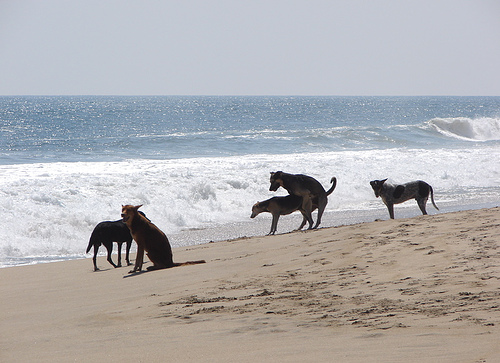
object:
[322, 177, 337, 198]
tail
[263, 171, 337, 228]
dog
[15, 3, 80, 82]
sky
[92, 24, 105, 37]
skies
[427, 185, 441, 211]
tail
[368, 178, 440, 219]
dog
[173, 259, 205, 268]
tail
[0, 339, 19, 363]
ground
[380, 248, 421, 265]
ground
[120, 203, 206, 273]
brown dogs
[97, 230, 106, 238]
black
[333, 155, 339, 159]
white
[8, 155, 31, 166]
water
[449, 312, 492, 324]
footprints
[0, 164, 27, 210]
wave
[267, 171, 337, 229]
dog humped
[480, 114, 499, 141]
wave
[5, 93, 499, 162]
ocean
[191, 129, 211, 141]
waves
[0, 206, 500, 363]
beach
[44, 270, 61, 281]
sand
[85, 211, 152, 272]
dog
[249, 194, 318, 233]
dog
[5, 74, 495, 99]
distance